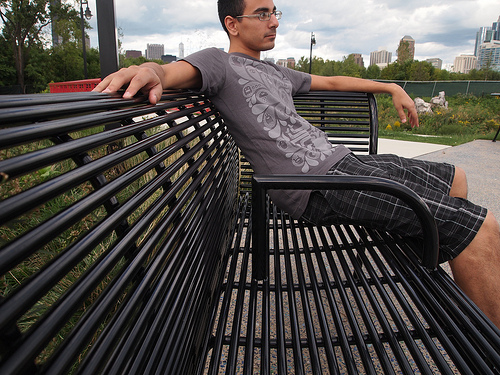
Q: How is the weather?
A: It is cloudy.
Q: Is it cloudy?
A: Yes, it is cloudy.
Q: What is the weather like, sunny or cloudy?
A: It is cloudy.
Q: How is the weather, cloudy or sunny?
A: It is cloudy.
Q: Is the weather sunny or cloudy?
A: It is cloudy.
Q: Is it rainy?
A: No, it is cloudy.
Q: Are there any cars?
A: No, there are no cars.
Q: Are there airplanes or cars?
A: No, there are no cars or airplanes.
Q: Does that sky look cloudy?
A: Yes, the sky is cloudy.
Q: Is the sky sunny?
A: No, the sky is cloudy.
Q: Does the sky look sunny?
A: No, the sky is cloudy.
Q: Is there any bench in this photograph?
A: Yes, there is a bench.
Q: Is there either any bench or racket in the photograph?
A: Yes, there is a bench.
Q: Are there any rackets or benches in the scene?
A: Yes, there is a bench.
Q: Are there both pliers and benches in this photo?
A: No, there is a bench but no pliers.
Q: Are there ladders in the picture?
A: No, there are no ladders.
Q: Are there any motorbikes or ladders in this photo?
A: No, there are no ladders or motorbikes.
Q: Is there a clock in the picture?
A: No, there are no clocks.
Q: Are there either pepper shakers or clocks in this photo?
A: No, there are no clocks or pepper shakers.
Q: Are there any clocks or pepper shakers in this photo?
A: No, there are no clocks or pepper shakers.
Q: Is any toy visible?
A: No, there are no toys.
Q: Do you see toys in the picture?
A: No, there are no toys.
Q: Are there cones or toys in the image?
A: No, there are no toys or cones.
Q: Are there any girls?
A: No, there are no girls.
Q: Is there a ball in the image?
A: No, there are no balls.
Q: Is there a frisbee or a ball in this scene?
A: No, there are no balls or frisbees.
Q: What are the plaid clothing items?
A: The clothing items are shorts.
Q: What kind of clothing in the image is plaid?
A: The clothing is shorts.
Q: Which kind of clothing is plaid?
A: The clothing is shorts.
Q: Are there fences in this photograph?
A: Yes, there is a fence.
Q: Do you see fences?
A: Yes, there is a fence.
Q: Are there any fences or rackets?
A: Yes, there is a fence.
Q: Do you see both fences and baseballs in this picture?
A: No, there is a fence but no baseballs.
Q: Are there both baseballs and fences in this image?
A: No, there is a fence but no baseballs.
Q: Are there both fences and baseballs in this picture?
A: No, there is a fence but no baseballs.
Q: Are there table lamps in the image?
A: No, there are no table lamps.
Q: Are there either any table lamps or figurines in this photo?
A: No, there are no table lamps or figurines.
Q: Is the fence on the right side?
A: Yes, the fence is on the right of the image.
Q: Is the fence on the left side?
A: No, the fence is on the right of the image.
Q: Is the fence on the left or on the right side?
A: The fence is on the right of the image.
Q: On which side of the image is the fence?
A: The fence is on the right of the image.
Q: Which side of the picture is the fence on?
A: The fence is on the right of the image.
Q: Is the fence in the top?
A: Yes, the fence is in the top of the image.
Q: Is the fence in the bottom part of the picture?
A: No, the fence is in the top of the image.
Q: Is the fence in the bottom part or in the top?
A: The fence is in the top of the image.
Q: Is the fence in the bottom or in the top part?
A: The fence is in the top of the image.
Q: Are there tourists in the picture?
A: No, there are no tourists.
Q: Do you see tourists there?
A: No, there are no tourists.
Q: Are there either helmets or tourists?
A: No, there are no tourists or helmets.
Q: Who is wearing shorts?
A: The man is wearing shorts.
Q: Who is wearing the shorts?
A: The man is wearing shorts.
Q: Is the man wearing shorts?
A: Yes, the man is wearing shorts.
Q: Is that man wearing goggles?
A: No, the man is wearing shorts.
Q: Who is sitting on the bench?
A: The man is sitting on the bench.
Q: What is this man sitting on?
A: The man is sitting on the bench.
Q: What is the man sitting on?
A: The man is sitting on the bench.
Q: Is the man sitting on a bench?
A: Yes, the man is sitting on a bench.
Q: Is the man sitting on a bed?
A: No, the man is sitting on a bench.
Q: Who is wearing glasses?
A: The man is wearing glasses.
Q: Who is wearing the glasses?
A: The man is wearing glasses.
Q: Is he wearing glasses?
A: Yes, the man is wearing glasses.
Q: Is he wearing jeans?
A: No, the man is wearing glasses.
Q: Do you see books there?
A: No, there are no books.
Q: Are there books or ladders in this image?
A: No, there are no books or ladders.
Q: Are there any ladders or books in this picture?
A: No, there are no books or ladders.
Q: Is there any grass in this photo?
A: Yes, there is grass.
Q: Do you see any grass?
A: Yes, there is grass.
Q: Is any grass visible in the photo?
A: Yes, there is grass.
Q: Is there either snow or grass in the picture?
A: Yes, there is grass.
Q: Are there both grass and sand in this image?
A: No, there is grass but no sand.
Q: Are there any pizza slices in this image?
A: No, there are no pizza slices.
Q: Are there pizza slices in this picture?
A: No, there are no pizza slices.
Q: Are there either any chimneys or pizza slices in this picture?
A: No, there are no pizza slices or chimneys.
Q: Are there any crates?
A: No, there are no crates.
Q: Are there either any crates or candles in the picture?
A: No, there are no crates or candles.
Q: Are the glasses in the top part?
A: Yes, the glasses are in the top of the image.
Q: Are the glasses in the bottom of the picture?
A: No, the glasses are in the top of the image.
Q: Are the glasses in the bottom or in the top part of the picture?
A: The glasses are in the top of the image.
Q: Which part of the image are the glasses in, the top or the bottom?
A: The glasses are in the top of the image.